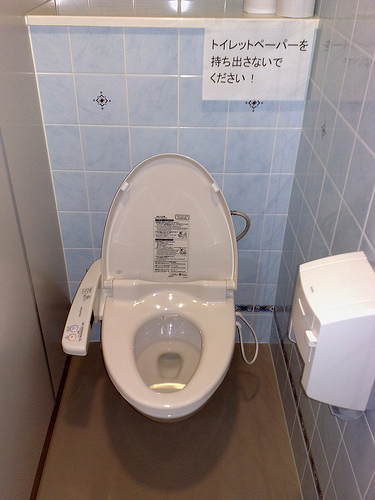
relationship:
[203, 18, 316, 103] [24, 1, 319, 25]
sign on shelf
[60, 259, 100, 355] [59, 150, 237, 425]
armrest on toilet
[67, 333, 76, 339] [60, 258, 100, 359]
button on an arm rest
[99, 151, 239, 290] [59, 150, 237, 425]
lid of a toilet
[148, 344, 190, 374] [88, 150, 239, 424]
water in a toilet